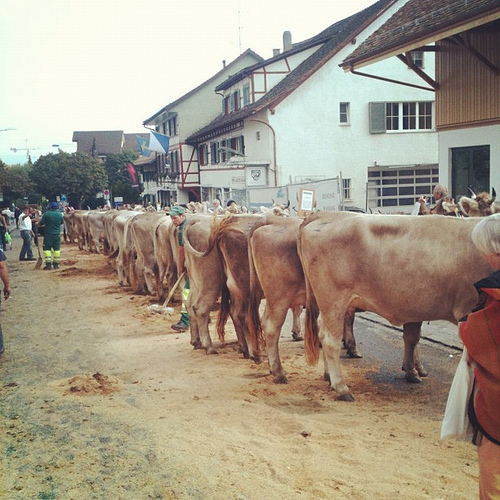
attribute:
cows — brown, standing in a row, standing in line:
[65, 189, 499, 402]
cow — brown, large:
[297, 211, 495, 404]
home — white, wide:
[186, 3, 437, 211]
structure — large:
[247, 170, 344, 218]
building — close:
[337, 1, 499, 208]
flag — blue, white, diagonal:
[148, 130, 169, 155]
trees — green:
[1, 138, 139, 211]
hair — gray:
[435, 186, 449, 200]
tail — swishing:
[183, 210, 239, 259]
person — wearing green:
[37, 202, 65, 271]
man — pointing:
[18, 206, 35, 261]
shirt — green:
[40, 209, 65, 233]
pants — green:
[43, 235, 61, 264]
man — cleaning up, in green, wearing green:
[167, 207, 192, 332]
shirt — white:
[18, 213, 32, 231]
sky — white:
[1, 1, 375, 159]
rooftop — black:
[187, 1, 399, 144]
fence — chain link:
[217, 188, 248, 217]